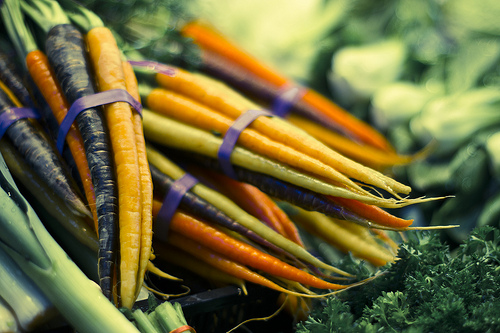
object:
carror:
[66, 0, 143, 310]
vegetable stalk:
[153, 300, 187, 333]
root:
[0, 0, 36, 58]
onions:
[0, 246, 52, 331]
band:
[218, 108, 272, 179]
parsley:
[294, 223, 500, 332]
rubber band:
[271, 86, 301, 115]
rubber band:
[154, 170, 198, 237]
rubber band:
[51, 87, 143, 154]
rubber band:
[0, 105, 45, 130]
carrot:
[141, 107, 380, 206]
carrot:
[0, 99, 94, 218]